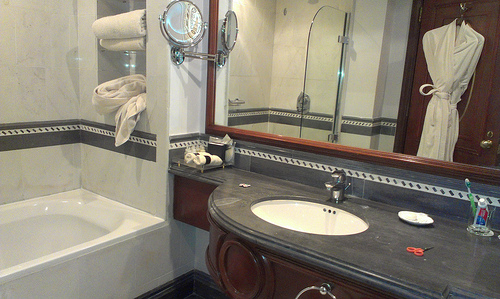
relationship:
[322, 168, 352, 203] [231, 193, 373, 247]
faucet above sink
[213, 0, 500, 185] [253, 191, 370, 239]
mirror next to sink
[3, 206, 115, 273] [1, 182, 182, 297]
water inside tub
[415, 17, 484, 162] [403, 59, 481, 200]
robe on hanger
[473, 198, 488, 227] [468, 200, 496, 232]
toothpaste in glass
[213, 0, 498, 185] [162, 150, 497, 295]
mirror above sink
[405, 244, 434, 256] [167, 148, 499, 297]
scissors on countertop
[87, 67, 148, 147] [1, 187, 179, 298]
towel above tub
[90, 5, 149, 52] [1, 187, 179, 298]
towel above tub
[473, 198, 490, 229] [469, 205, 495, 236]
toothpaste in glass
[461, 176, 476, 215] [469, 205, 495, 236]
brush in glass